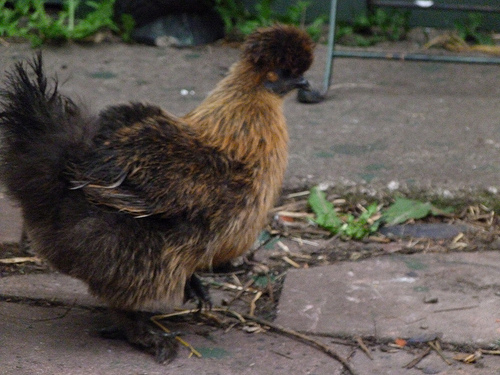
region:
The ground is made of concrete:
[328, 270, 489, 314]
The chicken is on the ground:
[0, 23, 359, 366]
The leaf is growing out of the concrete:
[308, 182, 440, 237]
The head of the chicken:
[234, 21, 321, 104]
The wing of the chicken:
[76, 95, 230, 220]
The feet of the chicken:
[94, 310, 187, 367]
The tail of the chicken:
[0, 45, 83, 204]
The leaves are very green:
[8, 1, 130, 50]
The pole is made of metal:
[303, 11, 485, 92]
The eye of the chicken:
[257, 64, 286, 89]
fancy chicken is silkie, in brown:
[0, 8, 322, 368]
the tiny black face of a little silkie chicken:
[260, 65, 313, 100]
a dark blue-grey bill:
[291, 78, 312, 94]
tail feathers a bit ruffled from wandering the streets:
[0, 46, 101, 205]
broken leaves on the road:
[294, 180, 447, 243]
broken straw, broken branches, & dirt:
[139, 177, 499, 374]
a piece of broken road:
[252, 238, 499, 373]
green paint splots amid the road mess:
[183, 228, 304, 371]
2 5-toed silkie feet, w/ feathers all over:
[79, 259, 218, 367]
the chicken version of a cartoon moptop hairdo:
[237, 17, 322, 79]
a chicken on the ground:
[2, 4, 331, 374]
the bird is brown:
[6, 16, 324, 373]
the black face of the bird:
[265, 64, 315, 103]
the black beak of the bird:
[291, 73, 313, 95]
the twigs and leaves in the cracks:
[280, 177, 499, 257]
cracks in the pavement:
[299, 106, 499, 373]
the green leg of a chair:
[308, 4, 341, 113]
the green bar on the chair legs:
[329, 44, 499, 74]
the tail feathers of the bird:
[0, 46, 87, 237]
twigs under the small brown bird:
[153, 297, 316, 369]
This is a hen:
[0, 15, 336, 370]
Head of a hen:
[243, 18, 320, 105]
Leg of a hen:
[155, 253, 217, 358]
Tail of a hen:
[6, 45, 97, 230]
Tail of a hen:
[80, 90, 238, 237]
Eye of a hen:
[259, 43, 288, 103]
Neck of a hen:
[215, 45, 277, 176]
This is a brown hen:
[4, 11, 346, 365]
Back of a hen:
[57, 83, 239, 182]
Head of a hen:
[17, 26, 383, 341]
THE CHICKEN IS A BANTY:
[3, 11, 323, 373]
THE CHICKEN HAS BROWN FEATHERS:
[128, 57, 303, 290]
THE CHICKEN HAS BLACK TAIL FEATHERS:
[0, 35, 92, 197]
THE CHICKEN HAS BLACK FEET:
[89, 263, 216, 370]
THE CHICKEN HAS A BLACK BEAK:
[291, 76, 314, 96]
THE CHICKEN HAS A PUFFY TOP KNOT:
[233, 20, 318, 111]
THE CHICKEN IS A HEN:
[0, 14, 325, 372]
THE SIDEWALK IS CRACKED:
[0, 153, 498, 373]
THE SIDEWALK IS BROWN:
[0, 35, 497, 370]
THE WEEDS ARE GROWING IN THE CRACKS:
[1, 165, 499, 373]